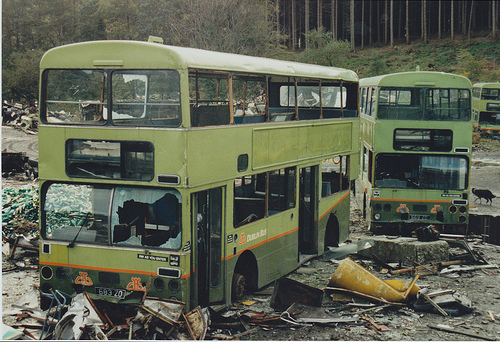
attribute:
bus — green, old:
[33, 46, 353, 283]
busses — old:
[25, 34, 374, 295]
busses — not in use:
[22, 31, 360, 311]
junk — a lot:
[7, 30, 497, 340]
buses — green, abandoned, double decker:
[30, 47, 482, 296]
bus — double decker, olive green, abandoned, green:
[29, 37, 358, 300]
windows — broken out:
[108, 173, 188, 249]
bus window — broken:
[107, 180, 189, 264]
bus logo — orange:
[112, 265, 152, 300]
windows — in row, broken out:
[179, 66, 363, 134]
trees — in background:
[7, 4, 487, 79]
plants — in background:
[7, 3, 497, 84]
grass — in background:
[290, 31, 494, 82]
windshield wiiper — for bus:
[59, 206, 99, 255]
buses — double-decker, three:
[15, 39, 499, 323]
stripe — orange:
[37, 254, 197, 284]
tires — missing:
[219, 249, 265, 314]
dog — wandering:
[460, 174, 493, 207]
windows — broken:
[171, 66, 349, 109]